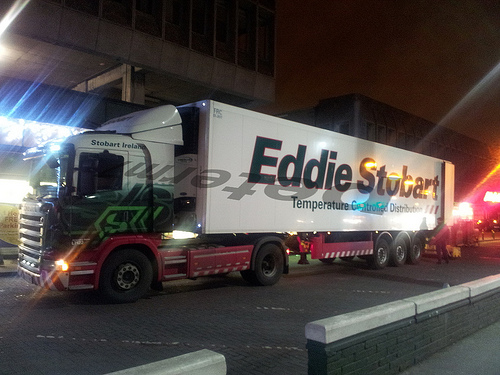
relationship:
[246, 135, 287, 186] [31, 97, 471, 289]
letter e on truck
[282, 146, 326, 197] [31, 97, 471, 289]
d's on truck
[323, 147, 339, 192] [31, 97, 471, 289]
i on truck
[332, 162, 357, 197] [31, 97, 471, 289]
e on truck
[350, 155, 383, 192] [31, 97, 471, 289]
s on truck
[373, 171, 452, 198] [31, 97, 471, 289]
t's on truck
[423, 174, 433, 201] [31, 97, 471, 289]
r on truck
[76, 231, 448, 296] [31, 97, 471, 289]
tires on truck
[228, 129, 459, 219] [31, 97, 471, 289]
name on truck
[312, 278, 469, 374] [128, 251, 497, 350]
wall along street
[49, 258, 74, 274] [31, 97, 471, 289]
lights on truck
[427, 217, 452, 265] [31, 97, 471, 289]
man by truck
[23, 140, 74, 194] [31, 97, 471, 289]
windshield on truck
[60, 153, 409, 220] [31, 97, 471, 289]
reflection on truck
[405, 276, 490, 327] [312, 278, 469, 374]
lines on wall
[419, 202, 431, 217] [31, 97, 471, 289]
gray square on truck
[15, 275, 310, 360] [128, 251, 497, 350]
lines across street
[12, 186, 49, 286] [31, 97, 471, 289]
large grill on truck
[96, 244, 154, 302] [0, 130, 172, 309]
tire in front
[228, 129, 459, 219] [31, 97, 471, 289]
eddie stobart on truck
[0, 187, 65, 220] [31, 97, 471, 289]
headlights on truck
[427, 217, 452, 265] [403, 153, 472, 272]
man at rear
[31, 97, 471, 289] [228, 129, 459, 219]
truck says eddie stobart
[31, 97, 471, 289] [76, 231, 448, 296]
truck has 5 wheels